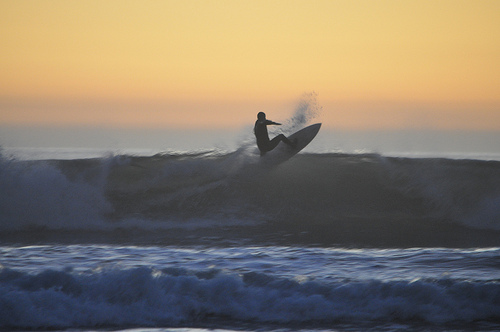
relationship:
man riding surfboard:
[253, 110, 290, 152] [293, 117, 322, 148]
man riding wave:
[253, 110, 290, 152] [10, 157, 489, 225]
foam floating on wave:
[11, 171, 82, 217] [10, 157, 489, 225]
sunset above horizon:
[23, 8, 492, 87] [10, 120, 247, 126]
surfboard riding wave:
[293, 117, 322, 148] [10, 157, 489, 225]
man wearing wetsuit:
[253, 110, 290, 152] [256, 128, 266, 147]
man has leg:
[253, 110, 290, 152] [275, 135, 290, 146]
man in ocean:
[253, 110, 290, 152] [8, 249, 496, 328]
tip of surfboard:
[319, 121, 324, 125] [293, 117, 322, 148]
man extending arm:
[253, 110, 290, 152] [265, 120, 280, 127]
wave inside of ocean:
[10, 157, 489, 225] [8, 249, 496, 328]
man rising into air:
[253, 110, 290, 152] [321, 130, 343, 153]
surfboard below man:
[293, 117, 322, 148] [253, 110, 290, 152]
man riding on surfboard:
[253, 110, 290, 152] [293, 117, 322, 148]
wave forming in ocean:
[10, 157, 489, 225] [8, 249, 496, 328]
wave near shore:
[10, 157, 489, 225] [163, 329, 166, 331]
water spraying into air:
[287, 100, 322, 124] [321, 130, 343, 153]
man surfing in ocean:
[253, 110, 290, 152] [8, 249, 496, 328]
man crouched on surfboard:
[253, 110, 290, 152] [293, 117, 322, 148]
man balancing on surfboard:
[253, 110, 290, 152] [293, 117, 322, 148]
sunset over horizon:
[23, 8, 492, 87] [10, 120, 247, 126]